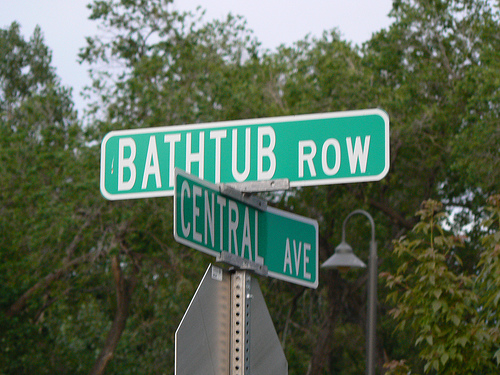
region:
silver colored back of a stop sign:
[162, 251, 292, 373]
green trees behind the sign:
[2, 3, 499, 373]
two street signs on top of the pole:
[95, 125, 415, 374]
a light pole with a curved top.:
[325, 204, 387, 374]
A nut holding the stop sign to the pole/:
[240, 286, 253, 301]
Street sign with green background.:
[95, 107, 394, 197]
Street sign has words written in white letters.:
[93, 106, 408, 201]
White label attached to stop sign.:
[209, 263, 225, 280]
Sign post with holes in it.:
[229, 268, 249, 373]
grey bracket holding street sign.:
[211, 246, 271, 278]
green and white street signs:
[98, 115, 388, 277]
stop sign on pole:
[173, 260, 287, 373]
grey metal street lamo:
[330, 209, 384, 373]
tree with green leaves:
[396, 200, 499, 369]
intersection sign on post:
[90, 108, 395, 280]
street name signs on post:
[99, 110, 387, 282]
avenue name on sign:
[280, 238, 312, 275]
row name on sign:
[294, 134, 371, 173]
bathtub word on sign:
[117, 130, 277, 182]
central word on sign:
[178, 180, 269, 260]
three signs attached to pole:
[91, 100, 392, 374]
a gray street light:
[317, 202, 381, 373]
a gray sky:
[1, 0, 498, 149]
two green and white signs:
[95, 110, 411, 316]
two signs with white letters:
[95, 106, 391, 289]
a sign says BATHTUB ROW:
[97, 106, 392, 203]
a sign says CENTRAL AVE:
[170, 163, 320, 293]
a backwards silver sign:
[167, 250, 289, 373]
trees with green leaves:
[1, 1, 496, 373]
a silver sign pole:
[224, 268, 253, 373]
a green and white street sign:
[98, 106, 390, 200]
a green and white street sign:
[171, 166, 321, 291]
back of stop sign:
[175, 261, 289, 373]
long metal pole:
[225, 265, 250, 372]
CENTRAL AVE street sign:
[167, 169, 320, 290]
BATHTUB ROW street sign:
[100, 107, 390, 199]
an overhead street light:
[317, 207, 383, 372]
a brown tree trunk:
[97, 254, 136, 371]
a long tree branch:
[0, 224, 106, 324]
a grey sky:
[0, 1, 422, 119]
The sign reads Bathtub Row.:
[100, 108, 390, 204]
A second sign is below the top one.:
[170, 168, 319, 292]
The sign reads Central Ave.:
[172, 169, 319, 289]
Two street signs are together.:
[97, 108, 389, 287]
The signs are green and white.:
[100, 106, 392, 288]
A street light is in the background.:
[320, 208, 377, 373]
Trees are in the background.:
[391, 0, 498, 374]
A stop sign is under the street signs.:
[174, 264, 288, 372]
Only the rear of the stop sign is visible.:
[172, 261, 288, 373]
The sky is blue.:
[251, 0, 376, 23]